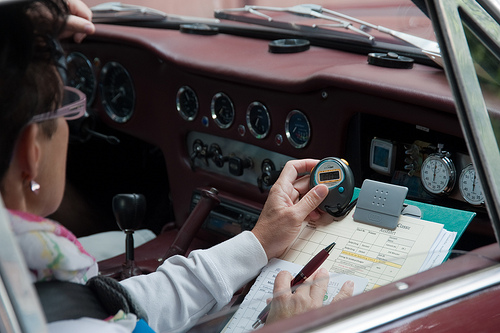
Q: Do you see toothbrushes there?
A: No, there are no toothbrushes.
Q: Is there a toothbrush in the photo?
A: No, there are no toothbrushes.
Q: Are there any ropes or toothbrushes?
A: No, there are no toothbrushes or ropes.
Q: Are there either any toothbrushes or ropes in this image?
A: No, there are no toothbrushes or ropes.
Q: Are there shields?
A: No, there are no shields.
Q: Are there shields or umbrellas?
A: No, there are no shields or umbrellas.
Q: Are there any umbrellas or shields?
A: No, there are no shields or umbrellas.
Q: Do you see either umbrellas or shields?
A: No, there are no shields or umbrellas.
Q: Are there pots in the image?
A: No, there are no pots.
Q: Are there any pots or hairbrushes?
A: No, there are no pots or hairbrushes.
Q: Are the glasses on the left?
A: Yes, the glasses are on the left of the image.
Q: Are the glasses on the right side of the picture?
A: No, the glasses are on the left of the image.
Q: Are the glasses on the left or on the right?
A: The glasses are on the left of the image.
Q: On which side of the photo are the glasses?
A: The glasses are on the left of the image.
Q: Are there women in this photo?
A: Yes, there is a woman.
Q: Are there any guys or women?
A: Yes, there is a woman.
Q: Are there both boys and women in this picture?
A: No, there is a woman but no boys.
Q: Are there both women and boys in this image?
A: No, there is a woman but no boys.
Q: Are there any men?
A: No, there are no men.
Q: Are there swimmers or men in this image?
A: No, there are no men or swimmers.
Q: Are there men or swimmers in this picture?
A: No, there are no men or swimmers.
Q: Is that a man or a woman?
A: That is a woman.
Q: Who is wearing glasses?
A: The woman is wearing glasses.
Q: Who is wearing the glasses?
A: The woman is wearing glasses.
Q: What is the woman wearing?
A: The woman is wearing glasses.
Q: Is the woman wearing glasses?
A: Yes, the woman is wearing glasses.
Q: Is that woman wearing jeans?
A: No, the woman is wearing glasses.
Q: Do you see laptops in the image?
A: No, there are no laptops.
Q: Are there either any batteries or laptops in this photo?
A: No, there are no laptops or batteries.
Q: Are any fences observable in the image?
A: No, there are no fences.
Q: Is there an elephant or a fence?
A: No, there are no fences or elephants.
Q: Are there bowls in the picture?
A: No, there are no bowls.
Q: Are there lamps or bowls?
A: No, there are no bowls or lamps.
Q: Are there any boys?
A: No, there are no boys.